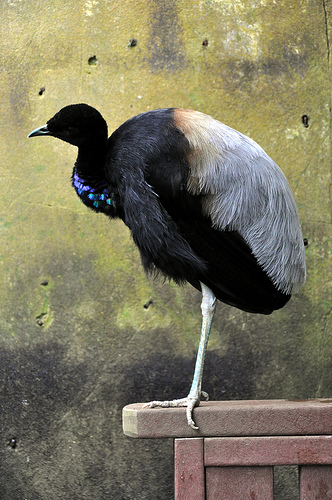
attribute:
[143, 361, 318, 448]
ledge — stone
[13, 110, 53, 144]
beak — gray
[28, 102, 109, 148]
head — black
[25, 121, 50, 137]
beak — black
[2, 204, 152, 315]
wall — green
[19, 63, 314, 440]
bird — big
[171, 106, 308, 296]
back — white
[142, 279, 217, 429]
white leg — long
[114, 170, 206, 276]
feather — big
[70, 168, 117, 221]
blocks — blue, green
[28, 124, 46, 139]
beak — shiny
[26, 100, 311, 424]
bird — grey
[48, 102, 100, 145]
head — black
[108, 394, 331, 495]
ledge — brown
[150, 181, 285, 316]
feathers — black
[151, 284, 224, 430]
leg — scaled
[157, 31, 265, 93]
shadow — black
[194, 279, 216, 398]
leg — long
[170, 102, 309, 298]
feathers — grey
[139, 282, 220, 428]
leg — grey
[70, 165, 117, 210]
feathers — blue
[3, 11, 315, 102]
glass — stained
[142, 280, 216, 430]
leg — grey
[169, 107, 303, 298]
plume — gray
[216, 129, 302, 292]
plume — white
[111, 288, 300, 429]
shadow — Green 